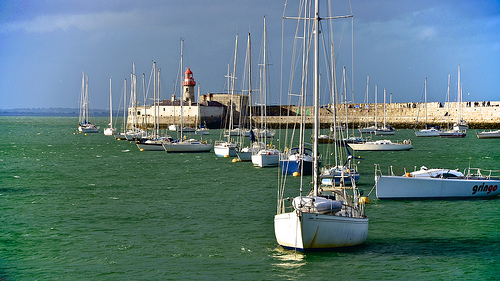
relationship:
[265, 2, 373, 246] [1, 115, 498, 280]
sailboat in water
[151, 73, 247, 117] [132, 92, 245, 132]
building of stone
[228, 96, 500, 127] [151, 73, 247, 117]
walkway behind building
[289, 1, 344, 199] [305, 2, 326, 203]
masts are made of metal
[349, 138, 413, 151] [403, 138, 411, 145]
boat has a motor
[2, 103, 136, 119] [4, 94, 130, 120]
mountains are in distance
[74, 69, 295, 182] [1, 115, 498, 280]
boats on water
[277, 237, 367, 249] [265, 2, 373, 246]
rust on ships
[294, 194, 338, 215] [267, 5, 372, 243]
raft on boat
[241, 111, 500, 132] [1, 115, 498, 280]
wall on water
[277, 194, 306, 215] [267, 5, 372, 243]
rail on boat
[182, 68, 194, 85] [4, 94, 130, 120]
lighthouse in distance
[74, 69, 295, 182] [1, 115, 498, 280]
boats in water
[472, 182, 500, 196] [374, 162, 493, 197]
gringe on boat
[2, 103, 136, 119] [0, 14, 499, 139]
mountains in background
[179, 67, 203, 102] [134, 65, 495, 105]
light house in back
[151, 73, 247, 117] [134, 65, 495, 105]
building in back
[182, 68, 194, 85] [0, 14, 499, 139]
lighthouse in background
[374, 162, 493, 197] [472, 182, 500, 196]
boat says gringo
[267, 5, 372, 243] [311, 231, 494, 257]
boat casting a shadow